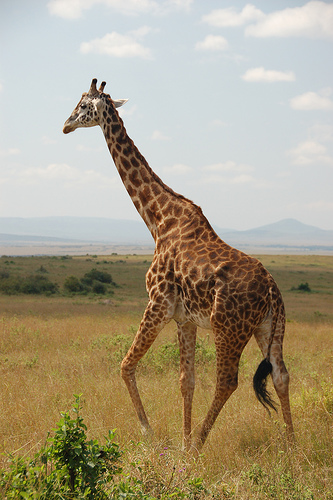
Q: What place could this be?
A: It is a field.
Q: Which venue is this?
A: This is a field.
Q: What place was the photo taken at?
A: It was taken at the field.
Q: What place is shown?
A: It is a field.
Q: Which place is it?
A: It is a field.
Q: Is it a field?
A: Yes, it is a field.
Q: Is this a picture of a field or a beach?
A: It is showing a field.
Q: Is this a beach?
A: No, it is a field.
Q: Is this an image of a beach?
A: No, the picture is showing a field.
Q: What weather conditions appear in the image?
A: It is cloudy.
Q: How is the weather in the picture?
A: It is cloudy.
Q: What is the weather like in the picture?
A: It is cloudy.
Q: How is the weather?
A: It is cloudy.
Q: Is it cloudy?
A: Yes, it is cloudy.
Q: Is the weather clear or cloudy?
A: It is cloudy.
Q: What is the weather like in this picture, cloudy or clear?
A: It is cloudy.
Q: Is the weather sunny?
A: No, it is cloudy.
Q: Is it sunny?
A: No, it is cloudy.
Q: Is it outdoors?
A: Yes, it is outdoors.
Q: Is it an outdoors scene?
A: Yes, it is outdoors.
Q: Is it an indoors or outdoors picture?
A: It is outdoors.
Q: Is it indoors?
A: No, it is outdoors.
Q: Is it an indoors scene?
A: No, it is outdoors.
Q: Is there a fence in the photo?
A: No, there are no fences.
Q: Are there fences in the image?
A: No, there are no fences.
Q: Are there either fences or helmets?
A: No, there are no fences or helmets.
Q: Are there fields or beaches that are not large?
A: No, there is a field but it is large.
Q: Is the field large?
A: Yes, the field is large.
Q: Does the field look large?
A: Yes, the field is large.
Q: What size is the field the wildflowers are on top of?
A: The field is large.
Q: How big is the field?
A: The field is large.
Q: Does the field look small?
A: No, the field is large.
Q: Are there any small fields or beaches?
A: No, there is a field but it is large.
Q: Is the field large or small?
A: The field is large.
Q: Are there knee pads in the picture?
A: No, there are no knee pads.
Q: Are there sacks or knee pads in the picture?
A: No, there are no knee pads or sacks.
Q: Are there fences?
A: No, there are no fences.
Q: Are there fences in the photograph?
A: No, there are no fences.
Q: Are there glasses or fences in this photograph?
A: No, there are no fences or glasses.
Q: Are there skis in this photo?
A: No, there are no skis.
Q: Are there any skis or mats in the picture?
A: No, there are no skis or mats.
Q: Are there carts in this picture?
A: No, there are no carts.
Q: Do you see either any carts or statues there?
A: No, there are no carts or statues.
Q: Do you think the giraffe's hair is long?
A: Yes, the hair is long.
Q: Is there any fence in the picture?
A: No, there are no fences.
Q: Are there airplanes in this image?
A: No, there are no airplanes.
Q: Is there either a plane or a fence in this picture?
A: No, there are no airplanes or fences.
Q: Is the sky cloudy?
A: Yes, the sky is cloudy.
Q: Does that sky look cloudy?
A: Yes, the sky is cloudy.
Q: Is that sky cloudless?
A: No, the sky is cloudy.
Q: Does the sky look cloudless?
A: No, the sky is cloudy.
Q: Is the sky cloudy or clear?
A: The sky is cloudy.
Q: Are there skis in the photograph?
A: No, there are no skis.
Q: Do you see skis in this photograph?
A: No, there are no skis.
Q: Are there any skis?
A: No, there are no skis.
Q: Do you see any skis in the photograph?
A: No, there are no skis.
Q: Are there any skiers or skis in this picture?
A: No, there are no skis or skiers.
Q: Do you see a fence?
A: No, there are no fences.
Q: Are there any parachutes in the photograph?
A: No, there are no parachutes.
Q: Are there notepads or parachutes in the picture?
A: No, there are no parachutes or notepads.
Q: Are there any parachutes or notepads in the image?
A: No, there are no parachutes or notepads.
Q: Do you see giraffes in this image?
A: Yes, there is a giraffe.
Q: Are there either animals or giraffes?
A: Yes, there is a giraffe.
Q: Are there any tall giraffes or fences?
A: Yes, there is a tall giraffe.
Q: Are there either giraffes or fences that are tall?
A: Yes, the giraffe is tall.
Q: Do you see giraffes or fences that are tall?
A: Yes, the giraffe is tall.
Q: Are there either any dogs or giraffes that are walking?
A: Yes, the giraffe is walking.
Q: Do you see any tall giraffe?
A: Yes, there is a tall giraffe.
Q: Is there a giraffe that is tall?
A: Yes, there is a giraffe that is tall.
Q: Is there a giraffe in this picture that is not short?
A: Yes, there is a tall giraffe.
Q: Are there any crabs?
A: No, there are no crabs.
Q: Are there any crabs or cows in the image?
A: No, there are no crabs or cows.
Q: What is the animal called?
A: The animal is a giraffe.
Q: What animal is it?
A: The animal is a giraffe.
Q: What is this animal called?
A: This is a giraffe.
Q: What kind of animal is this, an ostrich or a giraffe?
A: This is a giraffe.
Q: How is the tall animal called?
A: The animal is a giraffe.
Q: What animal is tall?
A: The animal is a giraffe.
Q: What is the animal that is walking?
A: The animal is a giraffe.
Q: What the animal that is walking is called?
A: The animal is a giraffe.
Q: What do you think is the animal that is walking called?
A: The animal is a giraffe.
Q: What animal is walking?
A: The animal is a giraffe.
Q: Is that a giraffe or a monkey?
A: That is a giraffe.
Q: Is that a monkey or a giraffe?
A: That is a giraffe.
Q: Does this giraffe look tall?
A: Yes, the giraffe is tall.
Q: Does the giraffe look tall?
A: Yes, the giraffe is tall.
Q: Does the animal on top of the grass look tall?
A: Yes, the giraffe is tall.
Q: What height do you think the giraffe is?
A: The giraffe is tall.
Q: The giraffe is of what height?
A: The giraffe is tall.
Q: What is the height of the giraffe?
A: The giraffe is tall.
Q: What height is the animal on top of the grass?
A: The giraffe is tall.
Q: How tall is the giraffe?
A: The giraffe is tall.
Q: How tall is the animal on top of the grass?
A: The giraffe is tall.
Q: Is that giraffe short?
A: No, the giraffe is tall.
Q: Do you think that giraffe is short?
A: No, the giraffe is tall.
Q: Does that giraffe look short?
A: No, the giraffe is tall.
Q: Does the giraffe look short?
A: No, the giraffe is tall.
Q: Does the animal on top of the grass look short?
A: No, the giraffe is tall.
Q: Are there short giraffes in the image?
A: No, there is a giraffe but it is tall.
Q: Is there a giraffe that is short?
A: No, there is a giraffe but it is tall.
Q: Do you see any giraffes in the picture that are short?
A: No, there is a giraffe but it is tall.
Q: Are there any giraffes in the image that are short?
A: No, there is a giraffe but it is tall.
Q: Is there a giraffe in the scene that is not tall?
A: No, there is a giraffe but it is tall.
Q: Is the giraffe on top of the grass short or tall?
A: The giraffe is tall.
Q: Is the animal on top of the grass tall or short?
A: The giraffe is tall.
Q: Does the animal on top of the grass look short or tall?
A: The giraffe is tall.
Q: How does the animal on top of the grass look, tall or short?
A: The giraffe is tall.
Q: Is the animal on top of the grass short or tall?
A: The giraffe is tall.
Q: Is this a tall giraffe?
A: Yes, this is a tall giraffe.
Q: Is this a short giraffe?
A: No, this is a tall giraffe.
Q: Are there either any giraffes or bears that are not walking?
A: No, there is a giraffe but it is walking.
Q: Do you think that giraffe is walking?
A: Yes, the giraffe is walking.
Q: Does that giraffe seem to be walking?
A: Yes, the giraffe is walking.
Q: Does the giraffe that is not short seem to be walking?
A: Yes, the giraffe is walking.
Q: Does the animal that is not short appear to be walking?
A: Yes, the giraffe is walking.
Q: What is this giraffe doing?
A: The giraffe is walking.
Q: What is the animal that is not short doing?
A: The giraffe is walking.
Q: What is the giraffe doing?
A: The giraffe is walking.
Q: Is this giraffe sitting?
A: No, the giraffe is walking.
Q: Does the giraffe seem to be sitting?
A: No, the giraffe is walking.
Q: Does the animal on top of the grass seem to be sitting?
A: No, the giraffe is walking.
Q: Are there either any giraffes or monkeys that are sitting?
A: No, there is a giraffe but it is walking.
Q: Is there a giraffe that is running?
A: No, there is a giraffe but it is walking.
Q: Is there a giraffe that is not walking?
A: No, there is a giraffe but it is walking.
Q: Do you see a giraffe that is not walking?
A: No, there is a giraffe but it is walking.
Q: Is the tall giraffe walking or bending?
A: The giraffe is walking.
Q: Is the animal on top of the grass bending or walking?
A: The giraffe is walking.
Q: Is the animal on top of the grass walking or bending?
A: The giraffe is walking.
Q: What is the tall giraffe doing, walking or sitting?
A: The giraffe is walking.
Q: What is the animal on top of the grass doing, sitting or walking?
A: The giraffe is walking.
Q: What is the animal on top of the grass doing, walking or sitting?
A: The giraffe is walking.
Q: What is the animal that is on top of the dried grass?
A: The animal is a giraffe.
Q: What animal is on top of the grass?
A: The animal is a giraffe.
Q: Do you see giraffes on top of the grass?
A: Yes, there is a giraffe on top of the grass.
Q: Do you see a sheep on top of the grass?
A: No, there is a giraffe on top of the grass.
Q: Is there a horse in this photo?
A: No, there are no horses.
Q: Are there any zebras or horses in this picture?
A: No, there are no horses or zebras.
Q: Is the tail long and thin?
A: Yes, the tail is long and thin.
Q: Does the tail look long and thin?
A: Yes, the tail is long and thin.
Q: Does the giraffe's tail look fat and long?
A: No, the tail is long but thin.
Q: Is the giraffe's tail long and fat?
A: No, the tail is long but thin.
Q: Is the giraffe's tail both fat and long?
A: No, the tail is long but thin.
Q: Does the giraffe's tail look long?
A: Yes, the tail is long.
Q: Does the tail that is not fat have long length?
A: Yes, the tail is long.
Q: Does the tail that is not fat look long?
A: Yes, the tail is long.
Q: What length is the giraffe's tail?
A: The tail is long.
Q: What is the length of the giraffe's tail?
A: The tail is long.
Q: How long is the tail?
A: The tail is long.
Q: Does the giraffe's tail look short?
A: No, the tail is long.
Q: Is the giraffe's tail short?
A: No, the tail is long.